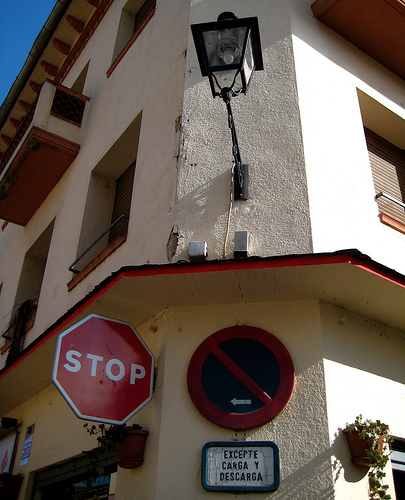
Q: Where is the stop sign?
A: On the wall.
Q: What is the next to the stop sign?
A: A plant.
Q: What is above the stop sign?
A: A light.